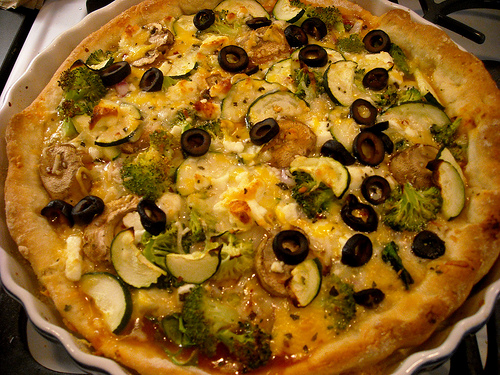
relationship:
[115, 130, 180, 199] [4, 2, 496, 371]
broccoli on pizza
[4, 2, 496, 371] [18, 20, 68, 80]
pizza in dish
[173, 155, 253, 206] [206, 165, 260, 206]
squash covered with cheese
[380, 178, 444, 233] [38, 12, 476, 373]
broccoli on cheese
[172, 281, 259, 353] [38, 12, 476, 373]
broccoli on cheese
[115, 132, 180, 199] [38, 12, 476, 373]
broccoli on cheese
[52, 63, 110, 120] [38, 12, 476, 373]
broccoli on cheese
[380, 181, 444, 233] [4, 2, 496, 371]
broccoli on pizza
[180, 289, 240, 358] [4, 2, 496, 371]
vegetable on pizza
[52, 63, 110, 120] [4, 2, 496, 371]
broccoli on pizza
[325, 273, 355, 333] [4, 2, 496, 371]
vegetable on pizza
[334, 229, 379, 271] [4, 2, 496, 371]
olive on pizza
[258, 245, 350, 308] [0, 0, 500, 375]
squash on pizza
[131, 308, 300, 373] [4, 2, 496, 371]
sauce on pizza